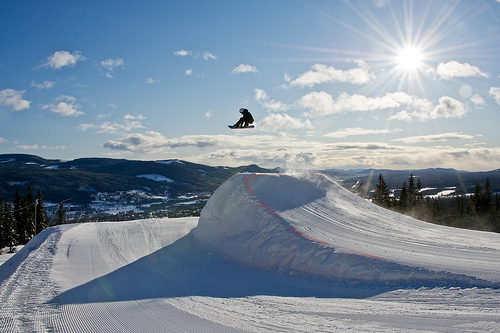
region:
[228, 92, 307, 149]
The man is doing tricks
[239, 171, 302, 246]
A red line is on the edge of the snow hill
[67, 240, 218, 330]
The snow is white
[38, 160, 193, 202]
Mountains are in the background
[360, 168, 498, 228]
Trees are on the side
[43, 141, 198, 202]
The snow is on the mountains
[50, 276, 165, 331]
Tires prints in the snow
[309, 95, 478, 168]
The clouds are white.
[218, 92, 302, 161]
A person on a snowboard.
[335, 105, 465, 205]
The day is sunny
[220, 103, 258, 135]
Snowboarder jumping in the air.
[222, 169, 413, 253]
A large slope for snowboarding.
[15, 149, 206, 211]
Mountains in the background.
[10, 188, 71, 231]
Pine trees in the background.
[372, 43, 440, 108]
The sun in the sky.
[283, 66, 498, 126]
Clouds in the sky.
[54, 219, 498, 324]
Snow on the ground.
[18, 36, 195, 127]
Blue sky above.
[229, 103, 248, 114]
Helmet on snowboarders head.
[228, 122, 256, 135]
Snowboard to ride on.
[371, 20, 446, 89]
Sun in blue sky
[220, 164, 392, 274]
Snow hill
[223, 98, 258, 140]
Snowboarder in mid air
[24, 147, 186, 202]
Lightly snow covered mountains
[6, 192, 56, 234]
Line of trees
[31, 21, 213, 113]
Blue sky with white clouds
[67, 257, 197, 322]
Shadow on ground from snow hill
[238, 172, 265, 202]
Red line on outer edge of snow hill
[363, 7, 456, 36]
Rays from the sun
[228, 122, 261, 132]
Snowboard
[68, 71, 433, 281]
snowboarder in air on top of mountain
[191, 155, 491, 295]
wide ramp made of snow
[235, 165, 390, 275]
red line on perimeter of ramp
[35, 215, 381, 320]
triangular shadow cast by ramp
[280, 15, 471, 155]
sun shining brightly above white clouds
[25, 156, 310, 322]
flatter surface next to ramp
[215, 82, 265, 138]
snowboarder facing front of board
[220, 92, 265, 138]
snowboarder crouched on board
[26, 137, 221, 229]
mountains with patches of snow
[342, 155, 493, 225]
trees in front of mountains and snow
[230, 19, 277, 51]
part of the sky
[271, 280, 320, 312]
part of a snow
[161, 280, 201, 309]
edge of a shadow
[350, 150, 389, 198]
part of some ray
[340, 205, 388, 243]
part of the ground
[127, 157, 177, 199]
part of some hills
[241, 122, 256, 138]
part of a skating board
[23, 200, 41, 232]
part of a post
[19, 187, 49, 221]
part of some trees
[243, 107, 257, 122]
part of a jumper